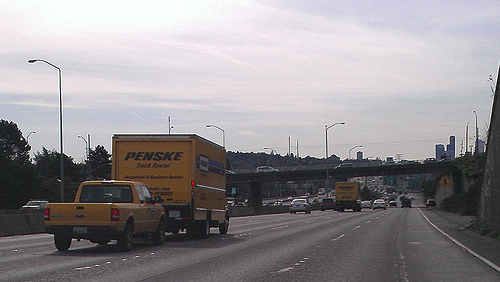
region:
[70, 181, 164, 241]
yellow pickup truck on freeway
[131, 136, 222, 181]
yellow black and blue moving truck on freeway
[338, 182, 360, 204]
yellow and black moving truck on freeway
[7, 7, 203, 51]
white clouds against blue sky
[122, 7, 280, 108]
white clouds against blue sky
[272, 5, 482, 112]
white clouds against blue sky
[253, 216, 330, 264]
gray pavement of freeway with white lane stripes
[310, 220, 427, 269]
gray pavement of freeway with white lane stripes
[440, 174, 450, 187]
yellow and black sign on freeway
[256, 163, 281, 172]
white car on bridge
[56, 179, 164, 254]
yellow pickup truck on highway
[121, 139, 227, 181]
yellow and black truck on highway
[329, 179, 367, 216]
yellow and black truck on highway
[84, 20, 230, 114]
white clouds against blue sky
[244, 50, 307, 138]
white clouds against blue sky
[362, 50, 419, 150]
white clouds against blue sky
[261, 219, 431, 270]
gray highway with white lane stripes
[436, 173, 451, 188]
yellow and black sign on highway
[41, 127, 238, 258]
a yellow moving truck pulling a truck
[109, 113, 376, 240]
two penske moving trucks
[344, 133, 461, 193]
tall buildings downtown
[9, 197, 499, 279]
four lanes going the same direction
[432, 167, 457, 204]
yellow sign with black arrow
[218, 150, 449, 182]
a road above the other road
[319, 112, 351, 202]
a metal street light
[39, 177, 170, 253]
small yellow ford truck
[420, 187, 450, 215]
car pulled over on the side of the road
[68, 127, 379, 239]
two trucks driving in the same lane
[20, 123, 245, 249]
bigger truck towing smaller trucky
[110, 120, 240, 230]
yellow moving truck in foreground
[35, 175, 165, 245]
yellow pickup truck being towed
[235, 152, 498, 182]
highway overpass in background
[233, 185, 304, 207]
traffic moving in opposite direction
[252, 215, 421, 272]
white lines on road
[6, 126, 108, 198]
view of trees on left side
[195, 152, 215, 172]
white logo with black letters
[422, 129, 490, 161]
view of tall buildings in background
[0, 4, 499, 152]
sky is sunny, partly cloudy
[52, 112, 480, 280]
vehicles on the road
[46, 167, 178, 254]
the truck is yellow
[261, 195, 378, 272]
lines painted on the ground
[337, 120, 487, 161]
buildings in the distance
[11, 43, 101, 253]
a tall lamp post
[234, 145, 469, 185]
cars on the interstate bridge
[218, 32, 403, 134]
the sky has clouds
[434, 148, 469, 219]
a traffic sign on the side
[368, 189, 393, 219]
a car is white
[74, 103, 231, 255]
bigger truck in front of smaller truck